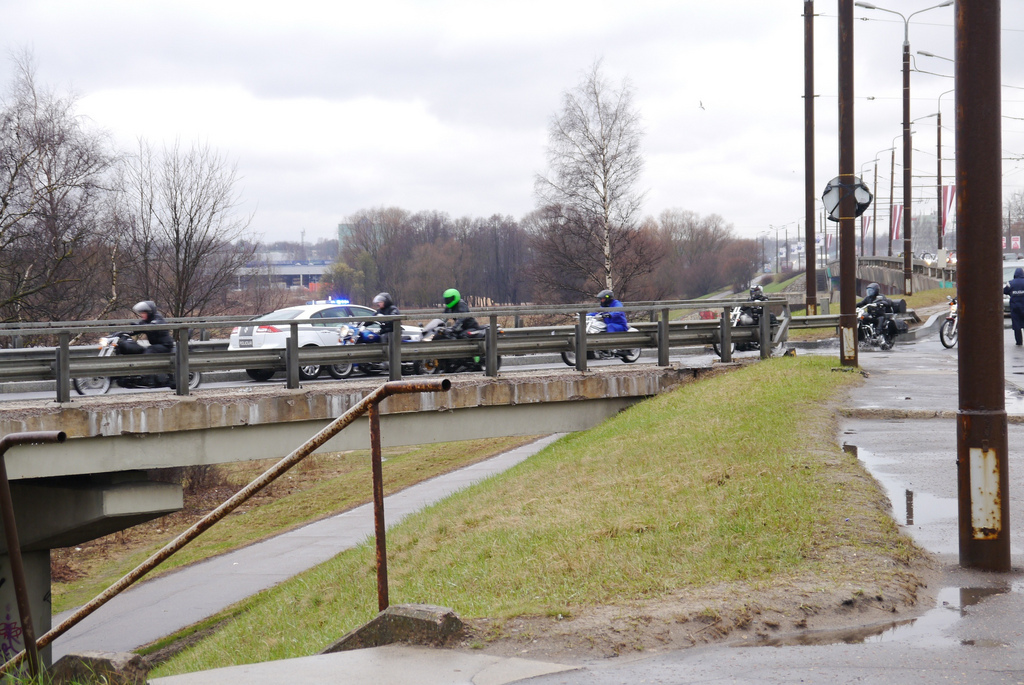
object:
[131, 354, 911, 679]
grass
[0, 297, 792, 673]
bridge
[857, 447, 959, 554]
puddle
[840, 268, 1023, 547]
road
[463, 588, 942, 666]
mud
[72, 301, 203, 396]
motorcycle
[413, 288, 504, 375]
motorcycle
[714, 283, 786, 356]
motorcycle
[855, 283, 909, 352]
motorcycle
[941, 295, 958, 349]
motorcycle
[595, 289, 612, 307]
helmet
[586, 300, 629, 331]
jacket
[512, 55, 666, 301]
tree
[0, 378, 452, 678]
handrail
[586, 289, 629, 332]
person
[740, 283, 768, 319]
person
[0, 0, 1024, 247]
sky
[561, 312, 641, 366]
motorcycle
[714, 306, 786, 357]
motorcycle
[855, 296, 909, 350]
motorcycle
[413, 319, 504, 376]
motorcycle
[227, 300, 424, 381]
car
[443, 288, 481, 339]
motorcycle rider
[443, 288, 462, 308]
helmet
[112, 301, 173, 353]
man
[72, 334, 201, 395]
motorcycle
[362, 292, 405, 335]
man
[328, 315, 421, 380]
motorcycle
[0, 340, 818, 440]
street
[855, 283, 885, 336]
person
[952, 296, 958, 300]
person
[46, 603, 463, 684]
stairs